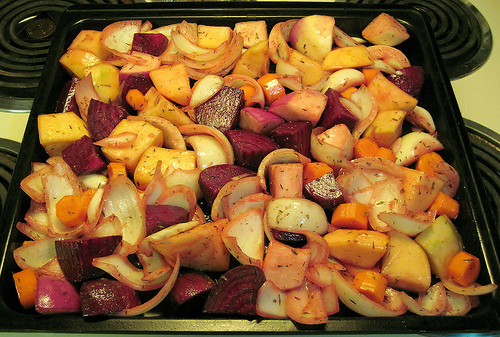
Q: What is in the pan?
A: Vegetables and potatoes.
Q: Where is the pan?
A: On the stovetop.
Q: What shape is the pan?
A: Rectangular.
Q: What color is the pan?
A: Black.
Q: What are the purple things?
A: Beets.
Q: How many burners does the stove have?
A: Four.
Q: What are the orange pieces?
A: Carrots.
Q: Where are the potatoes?
A: On the tray.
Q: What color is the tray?
A: Black.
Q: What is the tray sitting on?
A: Stove.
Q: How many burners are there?
A: 4.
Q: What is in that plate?
A: Radishes.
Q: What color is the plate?
A: Black.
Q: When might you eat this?
A: Dinner.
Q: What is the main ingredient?
A: Onions.